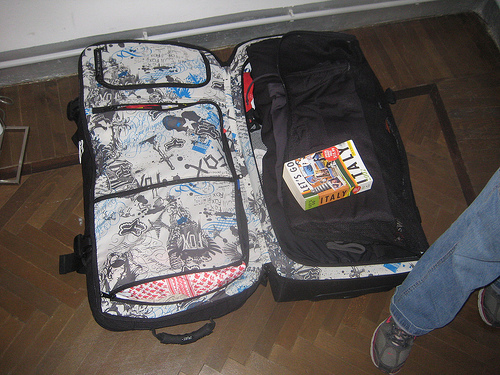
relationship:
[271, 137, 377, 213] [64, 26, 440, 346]
book on suitcase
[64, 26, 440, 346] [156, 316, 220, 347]
suitcase has handle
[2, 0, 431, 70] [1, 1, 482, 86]
pipe along wall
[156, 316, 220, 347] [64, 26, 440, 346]
handle on suitcase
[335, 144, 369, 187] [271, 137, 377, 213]
title of book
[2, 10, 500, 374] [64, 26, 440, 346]
floor below suitcase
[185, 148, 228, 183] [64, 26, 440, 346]
logo on suitcase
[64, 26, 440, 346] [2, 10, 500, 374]
suitcase on floor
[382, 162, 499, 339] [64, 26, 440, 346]
jeans next to suitcase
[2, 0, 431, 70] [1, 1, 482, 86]
pipe attached to wall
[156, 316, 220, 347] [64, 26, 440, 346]
handle of suitcase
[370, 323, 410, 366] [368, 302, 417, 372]
foot in shoe